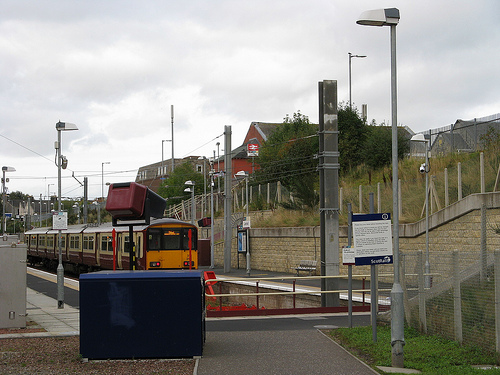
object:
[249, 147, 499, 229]
hill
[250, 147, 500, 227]
weeds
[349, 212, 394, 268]
sign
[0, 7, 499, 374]
city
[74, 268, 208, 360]
bin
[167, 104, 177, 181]
pole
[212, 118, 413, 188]
building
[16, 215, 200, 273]
train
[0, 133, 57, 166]
power line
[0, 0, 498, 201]
sky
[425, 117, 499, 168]
building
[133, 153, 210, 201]
building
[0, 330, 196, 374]
rocks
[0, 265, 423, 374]
ground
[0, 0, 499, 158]
clouds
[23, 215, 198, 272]
train stop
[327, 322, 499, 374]
grass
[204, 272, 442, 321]
railing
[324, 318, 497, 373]
patch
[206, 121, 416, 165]
roof